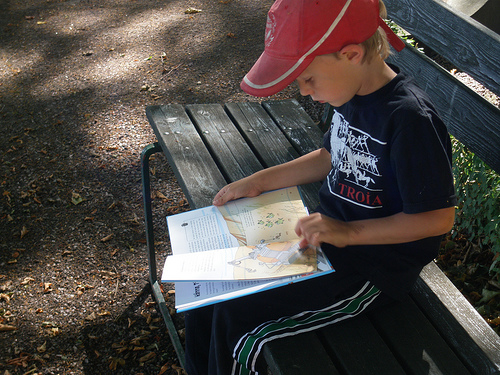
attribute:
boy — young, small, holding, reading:
[171, 1, 470, 375]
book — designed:
[152, 183, 341, 318]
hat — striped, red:
[236, 2, 412, 109]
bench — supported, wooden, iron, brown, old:
[117, 1, 500, 369]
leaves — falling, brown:
[13, 132, 121, 320]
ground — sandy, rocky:
[1, 1, 340, 374]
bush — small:
[416, 102, 497, 315]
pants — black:
[158, 258, 376, 375]